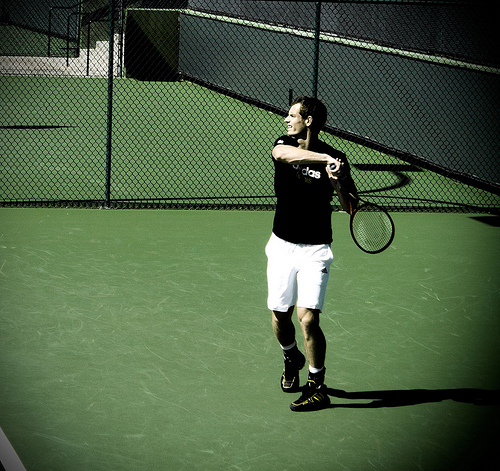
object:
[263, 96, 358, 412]
man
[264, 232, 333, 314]
shorts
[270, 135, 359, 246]
t shirt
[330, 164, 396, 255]
racket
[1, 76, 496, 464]
ground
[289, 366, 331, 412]
shoe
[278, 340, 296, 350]
sock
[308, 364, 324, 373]
sock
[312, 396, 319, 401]
stripe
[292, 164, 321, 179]
adidas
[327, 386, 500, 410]
shadow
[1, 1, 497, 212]
fence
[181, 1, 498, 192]
wall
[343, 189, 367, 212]
part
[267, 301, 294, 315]
edge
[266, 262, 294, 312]
part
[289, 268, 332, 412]
leg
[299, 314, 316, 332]
part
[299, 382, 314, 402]
lace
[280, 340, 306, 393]
shoe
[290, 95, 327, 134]
hair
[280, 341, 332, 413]
pair